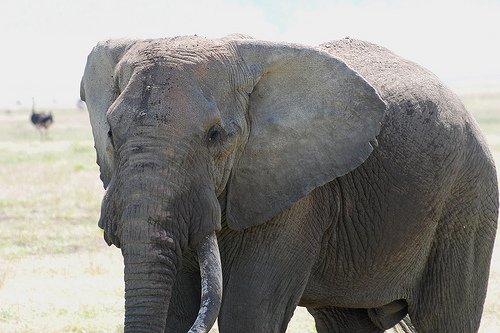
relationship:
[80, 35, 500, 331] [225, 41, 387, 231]
elephant has ear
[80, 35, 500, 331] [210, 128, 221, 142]
elephant has eye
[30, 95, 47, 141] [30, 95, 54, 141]
ostrich next to ostrich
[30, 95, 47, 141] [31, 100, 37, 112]
ostrich has neck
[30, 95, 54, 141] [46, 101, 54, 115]
ostrich has neck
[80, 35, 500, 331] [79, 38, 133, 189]
elephant has ear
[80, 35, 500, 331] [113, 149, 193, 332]
elephant has trunk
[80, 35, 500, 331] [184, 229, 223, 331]
elephant has tusk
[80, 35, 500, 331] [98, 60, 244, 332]
elephant has face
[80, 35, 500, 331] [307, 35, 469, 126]
elephant has back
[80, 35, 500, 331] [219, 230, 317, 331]
elephant has front leg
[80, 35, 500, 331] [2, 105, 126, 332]
elephant standing on field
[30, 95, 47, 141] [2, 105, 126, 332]
ostrich standing in field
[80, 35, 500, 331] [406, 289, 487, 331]
elephant has leg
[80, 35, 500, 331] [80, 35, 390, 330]
elephant has head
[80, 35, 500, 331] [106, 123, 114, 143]
elephant has eye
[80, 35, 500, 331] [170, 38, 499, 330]
elephant has body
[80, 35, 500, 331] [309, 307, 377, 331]
elephant has thigh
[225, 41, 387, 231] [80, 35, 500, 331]
ear part of elephant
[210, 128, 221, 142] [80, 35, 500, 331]
eye part of elephant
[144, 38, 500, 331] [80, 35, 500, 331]
side of elephant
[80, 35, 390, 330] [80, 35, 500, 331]
head part of elephant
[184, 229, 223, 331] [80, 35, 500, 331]
tusk part of elephant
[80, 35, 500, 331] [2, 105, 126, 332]
elephant standing in field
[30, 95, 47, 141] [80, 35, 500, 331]
ostrich behind elephant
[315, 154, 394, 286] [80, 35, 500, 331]
wrinkles visible on elephant